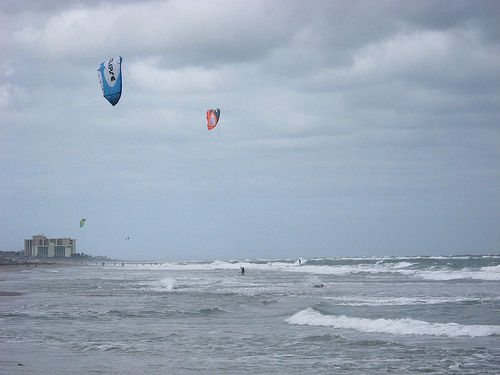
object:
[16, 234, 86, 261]
building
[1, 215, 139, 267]
background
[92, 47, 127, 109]
kite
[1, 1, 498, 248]
sky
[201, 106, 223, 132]
kite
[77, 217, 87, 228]
kite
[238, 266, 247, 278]
person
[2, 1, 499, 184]
clouds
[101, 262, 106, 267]
people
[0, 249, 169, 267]
shore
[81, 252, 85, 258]
trees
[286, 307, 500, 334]
waves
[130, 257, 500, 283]
waves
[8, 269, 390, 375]
part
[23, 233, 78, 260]
section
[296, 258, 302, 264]
black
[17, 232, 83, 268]
distance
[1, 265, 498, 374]
water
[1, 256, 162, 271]
beach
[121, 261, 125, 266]
person